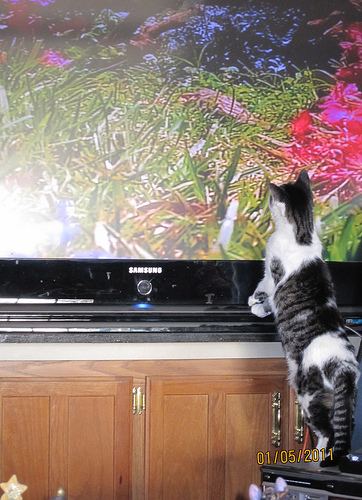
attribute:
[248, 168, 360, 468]
cat — gray, standing, white, black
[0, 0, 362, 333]
tv — flat screen, framed, black, on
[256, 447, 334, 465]
date — 01/05/2011, yellow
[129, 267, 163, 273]
logo — samsung, white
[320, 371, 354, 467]
tail — shades of gray, black, striped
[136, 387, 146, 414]
hinge — golden, metal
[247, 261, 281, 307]
front left leg — white, gray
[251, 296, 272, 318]
front right leg — white, gray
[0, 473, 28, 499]
star — yellow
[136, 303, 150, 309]
power light — blue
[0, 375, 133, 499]
door — wooden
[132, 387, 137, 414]
hinge — gold, metal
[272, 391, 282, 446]
handle — gold, golden, brass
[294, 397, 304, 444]
handle — gold, golden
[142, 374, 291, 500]
door — wooden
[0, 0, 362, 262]
flowers — pink, large, red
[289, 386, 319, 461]
door — wooden